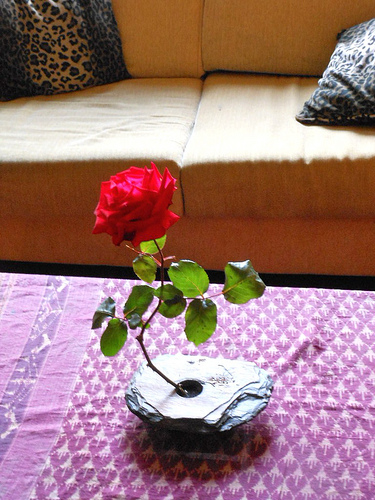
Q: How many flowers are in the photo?
A: 1.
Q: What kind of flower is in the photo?
A: Rose.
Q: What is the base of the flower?
A: A rock.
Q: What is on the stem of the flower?
A: Leaves.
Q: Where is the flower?
A: On a table.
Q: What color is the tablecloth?
A: Purple.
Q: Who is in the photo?
A: No one.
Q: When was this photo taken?
A: During the day.